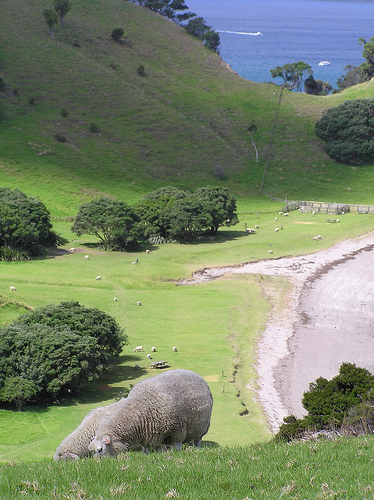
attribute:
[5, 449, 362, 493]
grass — green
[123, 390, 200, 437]
coat — fleece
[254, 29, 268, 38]
boat — powered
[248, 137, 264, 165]
log — wooden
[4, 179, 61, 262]
tree — green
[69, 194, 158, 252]
tree — green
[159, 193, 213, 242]
tree — green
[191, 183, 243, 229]
tree — green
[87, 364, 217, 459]
sheep — grey, wool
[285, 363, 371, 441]
tree — green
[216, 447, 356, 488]
grass — green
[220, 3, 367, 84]
water — dark blue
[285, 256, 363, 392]
sand — grey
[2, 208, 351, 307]
sheep — many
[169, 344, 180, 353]
sheep — white, grazing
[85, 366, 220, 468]
sheep — grazing, white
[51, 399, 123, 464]
sheep — white, grazing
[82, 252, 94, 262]
sheep — white, grazing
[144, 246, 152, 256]
sheep — grazing, white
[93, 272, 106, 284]
sheep — white, grazing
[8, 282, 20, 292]
sheep — grazing, white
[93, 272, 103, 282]
sheep — white, grazing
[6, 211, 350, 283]
field — green grass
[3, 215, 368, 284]
field — short grass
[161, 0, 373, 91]
water — pictured, blue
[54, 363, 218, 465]
sheep — eating, outdoors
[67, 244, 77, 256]
sheep — grazing, white